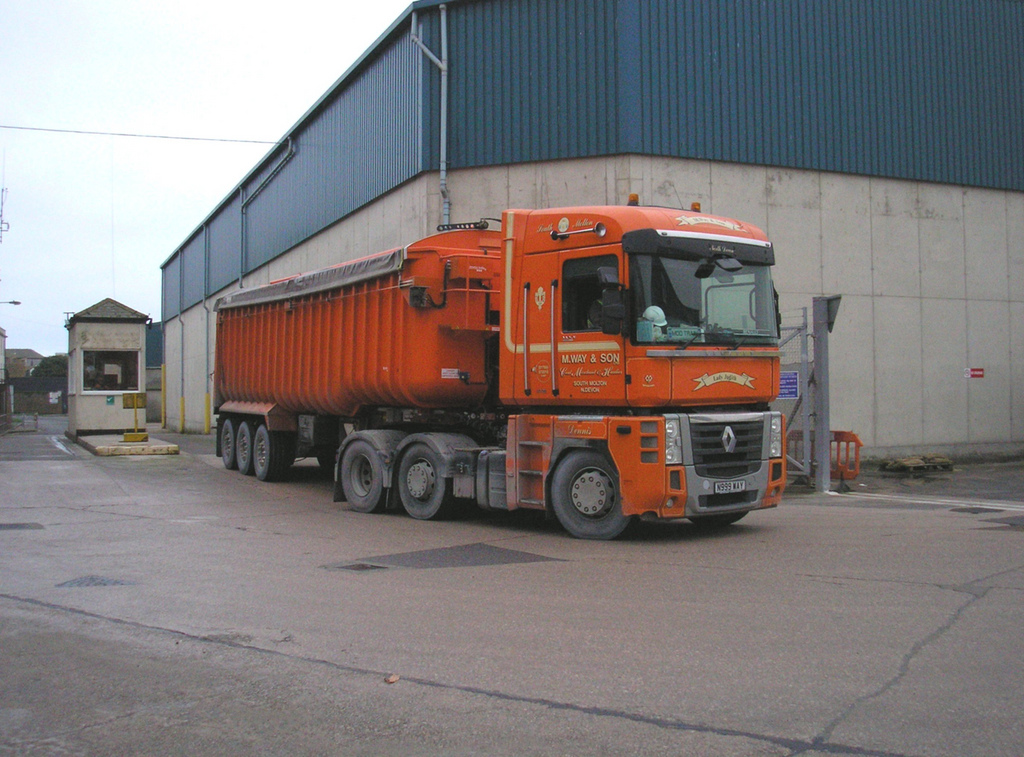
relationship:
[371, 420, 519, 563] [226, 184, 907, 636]
tire on truck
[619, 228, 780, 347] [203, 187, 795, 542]
window on truck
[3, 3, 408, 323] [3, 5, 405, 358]
cloud hanging in sky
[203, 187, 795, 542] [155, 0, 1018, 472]
truck near warehouse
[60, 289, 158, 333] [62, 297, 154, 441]
roof on ticket booth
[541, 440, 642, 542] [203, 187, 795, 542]
tire on truck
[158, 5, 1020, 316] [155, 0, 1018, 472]
roof on warehouse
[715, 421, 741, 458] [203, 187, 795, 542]
logo on truck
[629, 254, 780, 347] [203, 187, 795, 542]
window on truck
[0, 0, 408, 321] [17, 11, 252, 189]
cloud are in sky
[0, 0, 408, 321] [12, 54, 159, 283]
cloud are in sky